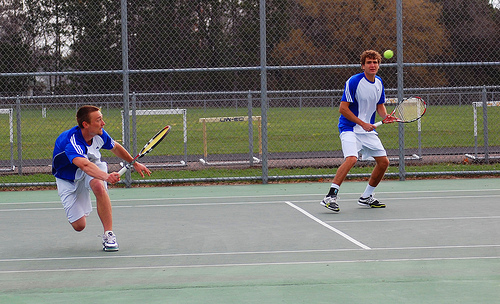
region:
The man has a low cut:
[73, 99, 97, 124]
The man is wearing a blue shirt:
[56, 128, 131, 183]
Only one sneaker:
[96, 229, 126, 256]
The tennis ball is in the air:
[374, 48, 399, 68]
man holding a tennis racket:
[49, 103, 171, 250]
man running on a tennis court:
[46, 103, 151, 256]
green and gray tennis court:
[1, 178, 497, 302]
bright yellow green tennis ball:
[382, 46, 394, 60]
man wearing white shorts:
[320, 45, 400, 215]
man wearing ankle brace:
[317, 45, 390, 211]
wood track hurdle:
[197, 111, 266, 168]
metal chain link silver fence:
[0, 0, 499, 192]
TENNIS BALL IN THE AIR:
[381, 50, 394, 60]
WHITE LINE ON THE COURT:
[320, 220, 336, 237]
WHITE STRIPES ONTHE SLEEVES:
[68, 134, 80, 151]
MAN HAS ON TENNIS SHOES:
[103, 233, 121, 250]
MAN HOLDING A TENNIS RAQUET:
[112, 125, 174, 186]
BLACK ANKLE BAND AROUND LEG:
[328, 185, 339, 197]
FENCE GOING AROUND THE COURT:
[175, 22, 242, 54]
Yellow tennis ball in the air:
[383, 48, 394, 58]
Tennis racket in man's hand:
[372, 94, 427, 131]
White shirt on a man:
[335, 130, 389, 157]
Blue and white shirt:
[342, 73, 382, 128]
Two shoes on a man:
[322, 195, 384, 211]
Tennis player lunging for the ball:
[48, 104, 170, 248]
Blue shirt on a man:
[52, 127, 111, 184]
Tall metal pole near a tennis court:
[259, 0, 269, 183]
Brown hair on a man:
[360, 48, 378, 61]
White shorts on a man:
[52, 168, 99, 225]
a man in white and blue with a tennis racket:
[45, 95, 179, 257]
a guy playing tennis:
[47, 105, 181, 255]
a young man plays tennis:
[318, 35, 432, 215]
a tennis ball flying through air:
[381, 40, 402, 65]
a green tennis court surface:
[127, 205, 498, 283]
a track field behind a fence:
[134, 80, 329, 172]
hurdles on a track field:
[118, 98, 270, 172]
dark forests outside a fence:
[8, 0, 342, 102]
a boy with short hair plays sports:
[44, 100, 181, 257]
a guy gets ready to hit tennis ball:
[318, 41, 430, 219]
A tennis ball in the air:
[377, 41, 399, 66]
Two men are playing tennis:
[45, 38, 435, 256]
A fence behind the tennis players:
[0, 0, 496, 192]